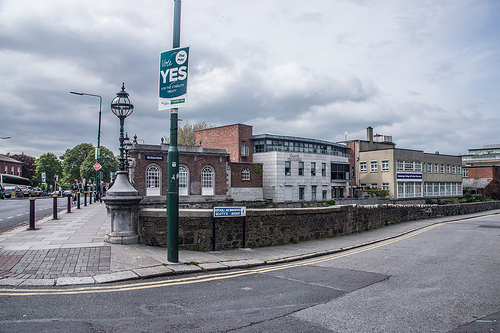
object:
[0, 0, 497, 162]
cloud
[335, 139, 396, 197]
building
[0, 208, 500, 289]
sidewalk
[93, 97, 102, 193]
lamp post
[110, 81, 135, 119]
lamp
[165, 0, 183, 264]
post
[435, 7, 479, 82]
beam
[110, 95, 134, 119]
globe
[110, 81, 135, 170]
post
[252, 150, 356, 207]
building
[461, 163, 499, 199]
building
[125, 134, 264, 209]
building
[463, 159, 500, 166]
building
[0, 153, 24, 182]
building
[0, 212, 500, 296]
line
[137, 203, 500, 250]
wall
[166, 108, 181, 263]
metal post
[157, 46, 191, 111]
advertisement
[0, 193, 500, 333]
ground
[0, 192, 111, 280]
side walk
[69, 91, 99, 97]
lamp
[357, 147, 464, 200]
building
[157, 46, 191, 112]
sign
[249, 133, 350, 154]
top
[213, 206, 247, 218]
board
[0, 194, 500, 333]
road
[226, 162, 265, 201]
wall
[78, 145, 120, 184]
trees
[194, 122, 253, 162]
buildings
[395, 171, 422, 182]
sign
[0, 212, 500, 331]
street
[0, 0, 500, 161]
sky